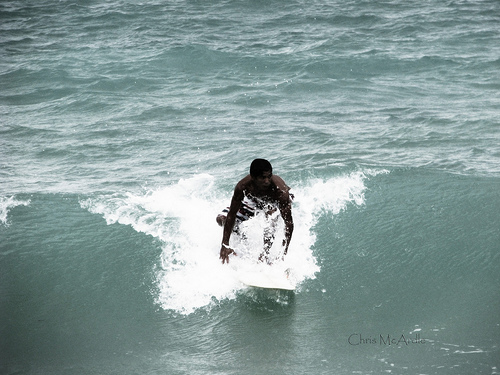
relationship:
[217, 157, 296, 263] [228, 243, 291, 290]
man on surfboard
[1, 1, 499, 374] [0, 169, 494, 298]
ocean has wave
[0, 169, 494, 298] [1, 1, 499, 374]
wave in ocean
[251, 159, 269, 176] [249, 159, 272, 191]
hair on head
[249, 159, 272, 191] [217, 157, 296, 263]
head of man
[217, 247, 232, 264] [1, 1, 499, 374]
hand in ocean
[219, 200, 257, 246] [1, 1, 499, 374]
leg in ocean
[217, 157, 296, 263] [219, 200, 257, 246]
man has leg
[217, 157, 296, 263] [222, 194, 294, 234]
man wearing trunks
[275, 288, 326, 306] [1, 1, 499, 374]
bubbles in ocean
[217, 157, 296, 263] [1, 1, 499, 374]
man on ocean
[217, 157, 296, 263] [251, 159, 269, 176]
man has hair